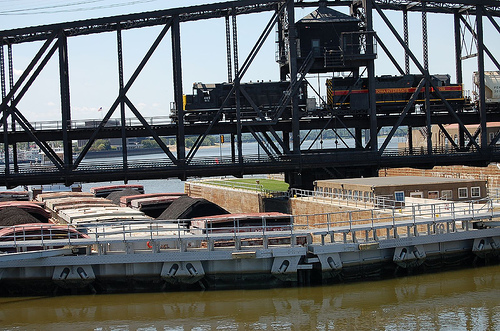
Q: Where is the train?
A: On the rail bridge.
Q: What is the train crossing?
A: River.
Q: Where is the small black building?
A: Above the train.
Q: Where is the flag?
A: On a building in the distance beyond the train bridge.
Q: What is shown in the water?
A: Reflection.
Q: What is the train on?
A: A bridge.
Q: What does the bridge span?
A: A river.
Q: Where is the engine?
A: At the front of the train.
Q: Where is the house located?
A: In the bridge.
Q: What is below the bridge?
A: A building.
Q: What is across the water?
A: Buildings.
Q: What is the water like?
A: Dirty.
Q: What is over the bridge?
A: Wires.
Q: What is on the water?
A: Reflections.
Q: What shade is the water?
A: Brown.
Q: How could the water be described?
A: Murky.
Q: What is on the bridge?
A: A train.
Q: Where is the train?
A: Above the water.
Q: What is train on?
A: Bridge.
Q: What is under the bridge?
A: Water.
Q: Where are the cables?
A: Hanging above bridge.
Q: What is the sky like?
A: Blue and clear.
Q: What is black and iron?
A: Frame of bridge.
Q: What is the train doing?
A: Traveling on bridge.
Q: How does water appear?
A: Calm.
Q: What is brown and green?
A: The water.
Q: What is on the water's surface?
A: A reflection.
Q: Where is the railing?
A: On the gray dock.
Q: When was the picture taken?
A: Daytime.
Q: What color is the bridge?
A: Black.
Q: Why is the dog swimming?
A: No dog.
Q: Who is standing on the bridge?
A: No one.